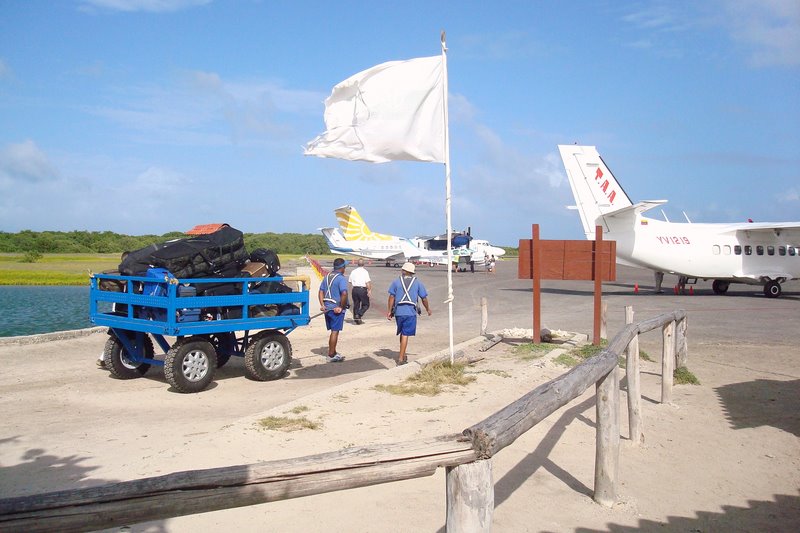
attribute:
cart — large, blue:
[90, 269, 309, 393]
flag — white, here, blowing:
[304, 36, 456, 363]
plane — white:
[559, 144, 797, 296]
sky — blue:
[2, 0, 798, 244]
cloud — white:
[82, 0, 208, 12]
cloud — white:
[5, 137, 61, 182]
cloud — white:
[104, 72, 325, 150]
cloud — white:
[621, 3, 797, 70]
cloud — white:
[454, 93, 575, 225]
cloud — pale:
[684, 149, 798, 167]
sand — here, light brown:
[251, 331, 599, 433]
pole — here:
[439, 32, 455, 369]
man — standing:
[384, 262, 433, 366]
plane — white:
[328, 208, 505, 272]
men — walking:
[321, 256, 433, 365]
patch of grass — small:
[412, 362, 462, 379]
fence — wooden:
[2, 315, 692, 532]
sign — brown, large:
[519, 226, 615, 345]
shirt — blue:
[391, 281, 425, 314]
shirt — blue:
[322, 275, 351, 314]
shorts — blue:
[396, 315, 419, 337]